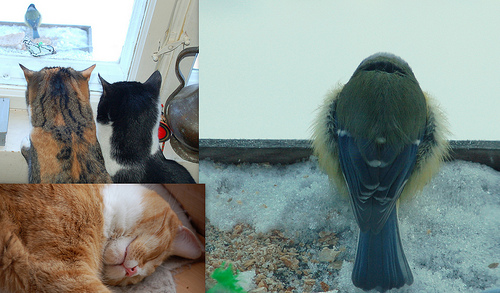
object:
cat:
[1, 184, 204, 291]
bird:
[308, 52, 453, 291]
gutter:
[199, 138, 499, 165]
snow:
[230, 173, 308, 220]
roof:
[202, 158, 498, 292]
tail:
[351, 198, 414, 292]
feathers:
[362, 72, 392, 167]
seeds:
[247, 254, 258, 260]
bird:
[24, 4, 41, 39]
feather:
[361, 208, 386, 288]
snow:
[218, 72, 312, 132]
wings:
[320, 87, 352, 187]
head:
[20, 63, 94, 109]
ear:
[80, 63, 96, 82]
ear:
[142, 69, 163, 98]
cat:
[95, 69, 197, 182]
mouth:
[107, 232, 136, 284]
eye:
[145, 255, 159, 263]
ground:
[216, 137, 498, 221]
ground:
[208, 233, 437, 291]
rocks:
[279, 255, 299, 270]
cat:
[15, 62, 111, 184]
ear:
[166, 222, 204, 262]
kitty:
[0, 186, 200, 291]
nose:
[123, 266, 138, 277]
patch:
[93, 184, 138, 243]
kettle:
[163, 46, 199, 163]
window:
[0, 2, 150, 86]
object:
[210, 261, 245, 293]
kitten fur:
[39, 203, 88, 254]